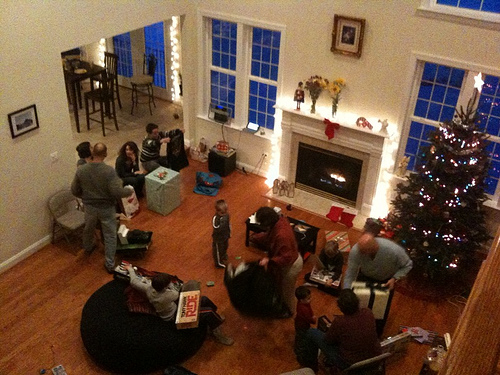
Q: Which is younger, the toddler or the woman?
A: The toddler is younger than the woman.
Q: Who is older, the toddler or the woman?
A: The woman is older than the toddler.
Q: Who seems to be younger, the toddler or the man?
A: The toddler is younger than the man.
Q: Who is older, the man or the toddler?
A: The man is older than the toddler.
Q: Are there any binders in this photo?
A: No, there are no binders.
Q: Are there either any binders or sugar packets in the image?
A: No, there are no binders or sugar packets.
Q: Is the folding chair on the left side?
A: Yes, the folding chair is on the left of the image.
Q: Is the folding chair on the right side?
A: No, the folding chair is on the left of the image.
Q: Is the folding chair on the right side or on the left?
A: The folding chair is on the left of the image.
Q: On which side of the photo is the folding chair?
A: The folding chair is on the left of the image.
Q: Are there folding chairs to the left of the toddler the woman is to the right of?
A: Yes, there is a folding chair to the left of the toddler.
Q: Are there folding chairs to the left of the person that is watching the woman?
A: Yes, there is a folding chair to the left of the toddler.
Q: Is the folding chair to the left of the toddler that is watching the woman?
A: Yes, the folding chair is to the left of the toddler.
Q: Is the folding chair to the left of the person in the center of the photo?
A: Yes, the folding chair is to the left of the toddler.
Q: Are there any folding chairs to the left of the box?
A: Yes, there is a folding chair to the left of the box.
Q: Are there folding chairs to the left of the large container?
A: Yes, there is a folding chair to the left of the box.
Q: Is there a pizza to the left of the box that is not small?
A: No, there is a folding chair to the left of the box.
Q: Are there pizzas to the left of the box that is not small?
A: No, there is a folding chair to the left of the box.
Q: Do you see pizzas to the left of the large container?
A: No, there is a folding chair to the left of the box.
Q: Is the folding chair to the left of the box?
A: Yes, the folding chair is to the left of the box.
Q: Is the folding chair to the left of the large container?
A: Yes, the folding chair is to the left of the box.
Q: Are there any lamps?
A: No, there are no lamps.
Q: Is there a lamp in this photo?
A: No, there are no lamps.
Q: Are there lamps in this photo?
A: No, there are no lamps.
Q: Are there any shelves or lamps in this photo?
A: No, there are no lamps or shelves.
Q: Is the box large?
A: Yes, the box is large.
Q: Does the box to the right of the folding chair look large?
A: Yes, the box is large.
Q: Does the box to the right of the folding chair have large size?
A: Yes, the box is large.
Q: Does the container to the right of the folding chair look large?
A: Yes, the box is large.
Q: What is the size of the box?
A: The box is large.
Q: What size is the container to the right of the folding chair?
A: The box is large.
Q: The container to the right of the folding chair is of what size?
A: The box is large.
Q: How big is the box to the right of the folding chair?
A: The box is large.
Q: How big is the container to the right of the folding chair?
A: The box is large.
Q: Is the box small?
A: No, the box is large.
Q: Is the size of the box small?
A: No, the box is large.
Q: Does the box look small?
A: No, the box is large.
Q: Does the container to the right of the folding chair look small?
A: No, the box is large.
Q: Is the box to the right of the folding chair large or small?
A: The box is large.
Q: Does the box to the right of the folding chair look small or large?
A: The box is large.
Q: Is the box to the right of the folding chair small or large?
A: The box is large.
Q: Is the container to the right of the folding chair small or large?
A: The box is large.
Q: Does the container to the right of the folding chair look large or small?
A: The box is large.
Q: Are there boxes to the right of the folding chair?
A: Yes, there is a box to the right of the folding chair.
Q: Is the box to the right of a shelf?
A: No, the box is to the right of the folding chair.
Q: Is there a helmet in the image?
A: No, there are no helmets.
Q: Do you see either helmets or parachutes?
A: No, there are no helmets or parachutes.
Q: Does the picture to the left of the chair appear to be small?
A: Yes, the picture is small.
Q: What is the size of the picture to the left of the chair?
A: The picture is small.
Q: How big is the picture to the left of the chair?
A: The picture is small.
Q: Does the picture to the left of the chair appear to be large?
A: No, the picture is small.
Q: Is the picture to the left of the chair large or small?
A: The picture is small.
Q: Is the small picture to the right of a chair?
A: No, the picture is to the left of a chair.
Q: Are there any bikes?
A: No, there are no bikes.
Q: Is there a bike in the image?
A: No, there are no bikes.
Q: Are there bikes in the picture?
A: No, there are no bikes.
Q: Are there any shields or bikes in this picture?
A: No, there are no bikes or shields.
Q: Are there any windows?
A: Yes, there is a window.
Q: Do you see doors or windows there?
A: Yes, there is a window.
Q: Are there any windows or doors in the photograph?
A: Yes, there is a window.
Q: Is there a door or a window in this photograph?
A: Yes, there is a window.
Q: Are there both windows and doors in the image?
A: No, there is a window but no doors.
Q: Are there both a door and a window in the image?
A: No, there is a window but no doors.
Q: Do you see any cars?
A: No, there are no cars.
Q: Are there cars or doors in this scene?
A: No, there are no cars or doors.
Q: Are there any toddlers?
A: Yes, there is a toddler.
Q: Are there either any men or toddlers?
A: Yes, there is a toddler.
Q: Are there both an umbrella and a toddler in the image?
A: No, there is a toddler but no umbrellas.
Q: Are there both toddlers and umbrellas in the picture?
A: No, there is a toddler but no umbrellas.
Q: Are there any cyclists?
A: No, there are no cyclists.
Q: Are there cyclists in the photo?
A: No, there are no cyclists.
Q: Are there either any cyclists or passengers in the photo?
A: No, there are no cyclists or passengers.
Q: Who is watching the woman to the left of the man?
A: The toddler is watching the woman.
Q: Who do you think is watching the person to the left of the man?
A: The toddler is watching the woman.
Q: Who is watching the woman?
A: The toddler is watching the woman.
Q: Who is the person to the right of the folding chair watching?
A: The toddler is watching the woman.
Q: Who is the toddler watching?
A: The toddler is watching the woman.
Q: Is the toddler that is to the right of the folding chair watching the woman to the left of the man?
A: Yes, the toddler is watching the woman.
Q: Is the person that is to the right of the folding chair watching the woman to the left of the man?
A: Yes, the toddler is watching the woman.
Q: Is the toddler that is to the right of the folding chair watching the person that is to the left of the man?
A: Yes, the toddler is watching the woman.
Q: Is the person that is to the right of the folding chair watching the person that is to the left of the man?
A: Yes, the toddler is watching the woman.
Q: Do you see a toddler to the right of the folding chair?
A: Yes, there is a toddler to the right of the folding chair.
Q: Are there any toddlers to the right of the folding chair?
A: Yes, there is a toddler to the right of the folding chair.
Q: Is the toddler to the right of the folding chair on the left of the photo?
A: Yes, the toddler is to the right of the folding chair.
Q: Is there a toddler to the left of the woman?
A: Yes, there is a toddler to the left of the woman.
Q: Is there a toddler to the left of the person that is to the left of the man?
A: Yes, there is a toddler to the left of the woman.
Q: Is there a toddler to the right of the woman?
A: No, the toddler is to the left of the woman.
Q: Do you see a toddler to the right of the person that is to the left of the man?
A: No, the toddler is to the left of the woman.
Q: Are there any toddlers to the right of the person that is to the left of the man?
A: No, the toddler is to the left of the woman.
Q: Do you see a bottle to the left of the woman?
A: No, there is a toddler to the left of the woman.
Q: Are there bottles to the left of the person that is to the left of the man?
A: No, there is a toddler to the left of the woman.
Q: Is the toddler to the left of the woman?
A: Yes, the toddler is to the left of the woman.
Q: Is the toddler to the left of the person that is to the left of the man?
A: Yes, the toddler is to the left of the woman.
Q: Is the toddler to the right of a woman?
A: No, the toddler is to the left of a woman.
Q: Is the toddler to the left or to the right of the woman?
A: The toddler is to the left of the woman.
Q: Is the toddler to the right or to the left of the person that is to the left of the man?
A: The toddler is to the left of the woman.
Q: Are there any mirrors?
A: No, there are no mirrors.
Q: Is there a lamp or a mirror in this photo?
A: No, there are no mirrors or lamps.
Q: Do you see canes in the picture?
A: No, there are no canes.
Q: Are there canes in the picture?
A: No, there are no canes.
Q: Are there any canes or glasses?
A: No, there are no canes or glasses.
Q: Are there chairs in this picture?
A: Yes, there is a chair.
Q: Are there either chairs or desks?
A: Yes, there is a chair.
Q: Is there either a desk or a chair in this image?
A: Yes, there is a chair.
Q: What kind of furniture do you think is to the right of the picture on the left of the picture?
A: The piece of furniture is a chair.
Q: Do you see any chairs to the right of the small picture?
A: Yes, there is a chair to the right of the picture.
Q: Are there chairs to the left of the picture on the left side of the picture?
A: No, the chair is to the right of the picture.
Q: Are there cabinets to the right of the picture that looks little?
A: No, there is a chair to the right of the picture.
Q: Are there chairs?
A: Yes, there is a chair.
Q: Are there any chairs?
A: Yes, there is a chair.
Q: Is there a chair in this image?
A: Yes, there is a chair.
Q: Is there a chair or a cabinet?
A: Yes, there is a chair.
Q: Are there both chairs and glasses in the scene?
A: No, there is a chair but no glasses.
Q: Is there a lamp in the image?
A: No, there are no lamps.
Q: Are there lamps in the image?
A: No, there are no lamps.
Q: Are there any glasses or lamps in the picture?
A: No, there are no lamps or glasses.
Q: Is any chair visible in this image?
A: Yes, there is a chair.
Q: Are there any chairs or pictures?
A: Yes, there is a chair.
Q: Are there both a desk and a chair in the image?
A: No, there is a chair but no desks.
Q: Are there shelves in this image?
A: No, there are no shelves.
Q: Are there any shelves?
A: No, there are no shelves.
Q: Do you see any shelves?
A: No, there are no shelves.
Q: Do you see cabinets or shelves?
A: No, there are no shelves or cabinets.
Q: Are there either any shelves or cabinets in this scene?
A: No, there are no shelves or cabinets.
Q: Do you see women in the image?
A: Yes, there is a woman.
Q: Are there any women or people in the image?
A: Yes, there is a woman.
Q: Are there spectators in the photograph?
A: No, there are no spectators.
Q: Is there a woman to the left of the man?
A: Yes, there is a woman to the left of the man.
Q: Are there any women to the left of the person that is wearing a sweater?
A: Yes, there is a woman to the left of the man.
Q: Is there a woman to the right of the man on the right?
A: No, the woman is to the left of the man.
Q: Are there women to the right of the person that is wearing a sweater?
A: No, the woman is to the left of the man.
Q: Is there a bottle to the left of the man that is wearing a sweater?
A: No, there is a woman to the left of the man.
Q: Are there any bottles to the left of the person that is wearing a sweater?
A: No, there is a woman to the left of the man.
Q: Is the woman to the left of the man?
A: Yes, the woman is to the left of the man.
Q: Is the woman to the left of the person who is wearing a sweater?
A: Yes, the woman is to the left of the man.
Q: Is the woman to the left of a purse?
A: No, the woman is to the left of the man.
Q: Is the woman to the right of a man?
A: No, the woman is to the left of a man.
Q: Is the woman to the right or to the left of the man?
A: The woman is to the left of the man.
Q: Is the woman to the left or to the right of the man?
A: The woman is to the left of the man.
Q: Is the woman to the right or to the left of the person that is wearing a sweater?
A: The woman is to the left of the man.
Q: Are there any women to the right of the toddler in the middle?
A: Yes, there is a woman to the right of the toddler.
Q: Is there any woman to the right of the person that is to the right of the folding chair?
A: Yes, there is a woman to the right of the toddler.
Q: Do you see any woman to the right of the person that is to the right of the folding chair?
A: Yes, there is a woman to the right of the toddler.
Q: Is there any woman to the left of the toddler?
A: No, the woman is to the right of the toddler.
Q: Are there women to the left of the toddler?
A: No, the woman is to the right of the toddler.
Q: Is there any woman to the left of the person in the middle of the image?
A: No, the woman is to the right of the toddler.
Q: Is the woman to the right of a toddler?
A: Yes, the woman is to the right of a toddler.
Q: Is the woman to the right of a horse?
A: No, the woman is to the right of a toddler.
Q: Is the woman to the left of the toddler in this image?
A: No, the woman is to the right of the toddler.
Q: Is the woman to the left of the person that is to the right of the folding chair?
A: No, the woman is to the right of the toddler.